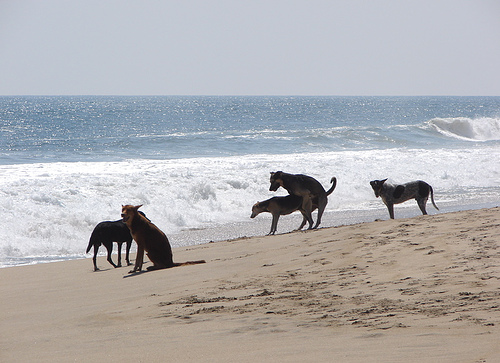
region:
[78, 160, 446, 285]
dogs with beach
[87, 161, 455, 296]
black, brown and white color dogs in the beach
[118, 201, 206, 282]
brown color dog is sitting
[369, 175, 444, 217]
dog focusing the camera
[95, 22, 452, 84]
sky with clouds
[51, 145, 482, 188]
big waves in the sea water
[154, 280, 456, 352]
wet sand near the sea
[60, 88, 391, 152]
blue color sea water with small waves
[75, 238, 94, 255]
tail of the dog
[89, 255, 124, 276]
legs of the dog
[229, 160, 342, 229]
one dog humping other dog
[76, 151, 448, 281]
five dogs on the beach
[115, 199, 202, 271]
dog sitting on the beach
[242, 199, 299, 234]
dog getting humped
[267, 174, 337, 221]
dog doing the humping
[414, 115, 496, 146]
wave breaking into ocean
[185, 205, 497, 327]
footprints in the sand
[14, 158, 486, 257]
wave crashing onto shore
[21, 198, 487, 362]
sand dogs are standing on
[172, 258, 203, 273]
tail of dog sitting down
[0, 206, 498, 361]
tan sand on the beach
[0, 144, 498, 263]
white foam of the water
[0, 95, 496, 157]
calm area of the ocean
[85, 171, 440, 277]
six dogs on the sand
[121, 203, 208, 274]
brown dog at the beach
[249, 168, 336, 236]
two dogs attached to each other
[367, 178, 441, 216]
black and white dog on the beach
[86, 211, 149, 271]
black dog behind brown dog on the beach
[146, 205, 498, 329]
footprints in the sand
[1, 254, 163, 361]
clear area of sand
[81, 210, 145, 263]
The black dog on the left.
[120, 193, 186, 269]
The brown dog on the left.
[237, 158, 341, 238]
The two dogs in the middle.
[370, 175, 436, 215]
The dog on the right.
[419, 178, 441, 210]
The tail of the dog on the right.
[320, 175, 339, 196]
The tail of the dog in the middle.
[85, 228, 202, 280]
The tails of the dogs on the left.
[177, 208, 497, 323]
The footprints in the sand.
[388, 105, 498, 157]
The wave in the water on the right.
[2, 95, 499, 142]
The water in the distance.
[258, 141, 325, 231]
dogs having sex on beach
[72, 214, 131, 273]
dog on sandy beach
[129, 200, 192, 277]
dog on sandy beach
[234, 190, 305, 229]
dog on sandy beach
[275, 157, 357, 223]
dog on sandy beach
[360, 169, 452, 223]
dog on sandy beach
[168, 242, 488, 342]
foot prints on sandy beach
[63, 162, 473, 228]
white crashing wave on beach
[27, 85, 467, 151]
calm blue waters in ocean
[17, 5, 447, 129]
gray skies overhead